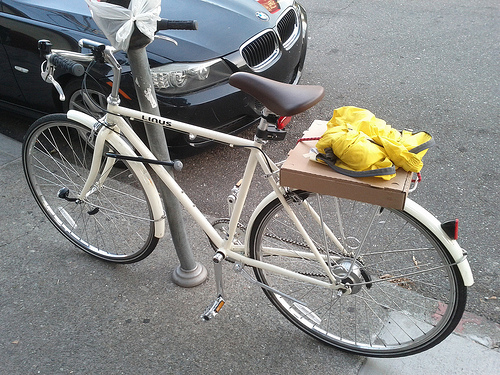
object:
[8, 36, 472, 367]
motorcycle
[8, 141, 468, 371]
field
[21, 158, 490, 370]
post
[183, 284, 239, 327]
pedal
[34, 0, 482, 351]
bicycle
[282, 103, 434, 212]
cardboard box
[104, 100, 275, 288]
frame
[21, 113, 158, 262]
tire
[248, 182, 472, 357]
tire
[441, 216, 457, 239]
reflector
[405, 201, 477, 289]
back fender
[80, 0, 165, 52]
plastic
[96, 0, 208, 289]
pole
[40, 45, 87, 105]
handlebar grip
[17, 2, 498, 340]
street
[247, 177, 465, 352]
wheel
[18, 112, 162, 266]
wheel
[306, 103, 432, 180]
bag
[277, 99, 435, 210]
box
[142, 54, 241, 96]
headlights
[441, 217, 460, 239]
light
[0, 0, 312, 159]
car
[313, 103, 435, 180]
material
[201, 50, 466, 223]
road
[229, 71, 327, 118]
seat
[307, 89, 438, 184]
item